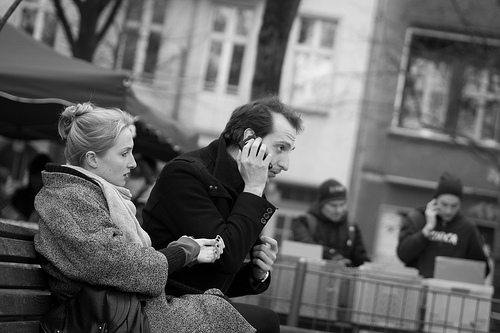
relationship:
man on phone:
[137, 94, 310, 332] [235, 131, 274, 176]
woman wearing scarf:
[29, 97, 260, 333] [57, 156, 156, 254]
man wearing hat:
[392, 170, 494, 284] [429, 166, 465, 206]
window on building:
[275, 7, 349, 121] [173, 1, 386, 263]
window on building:
[197, 1, 262, 106] [173, 1, 386, 263]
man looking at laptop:
[392, 170, 494, 284] [427, 249, 490, 287]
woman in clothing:
[29, 97, 260, 333] [31, 164, 257, 333]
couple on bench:
[28, 90, 305, 333] [1, 213, 72, 332]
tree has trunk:
[244, 1, 308, 108] [246, 1, 307, 105]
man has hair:
[137, 94, 310, 332] [217, 92, 308, 154]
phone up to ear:
[235, 131, 274, 176] [237, 125, 260, 142]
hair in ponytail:
[55, 97, 140, 168] [55, 97, 96, 144]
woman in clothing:
[29, 97, 260, 333] [31, 155, 263, 332]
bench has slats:
[1, 213, 72, 332] [1, 219, 53, 332]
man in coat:
[137, 94, 310, 332] [139, 133, 273, 306]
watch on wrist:
[255, 268, 272, 290] [251, 269, 270, 288]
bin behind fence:
[349, 255, 427, 332] [228, 255, 499, 332]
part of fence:
[317, 265, 363, 330] [228, 255, 499, 332]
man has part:
[395, 206, 490, 286] [403, 235, 426, 257]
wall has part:
[345, 2, 500, 332] [374, 146, 412, 162]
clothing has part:
[31, 164, 257, 333] [61, 226, 99, 274]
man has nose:
[137, 94, 310, 332] [276, 152, 291, 174]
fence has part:
[228, 255, 499, 332] [317, 265, 363, 330]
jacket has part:
[139, 133, 273, 306] [171, 190, 205, 223]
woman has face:
[29, 97, 260, 333] [82, 120, 141, 191]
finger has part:
[257, 232, 282, 254] [260, 233, 270, 245]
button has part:
[262, 204, 277, 217] [271, 205, 275, 216]